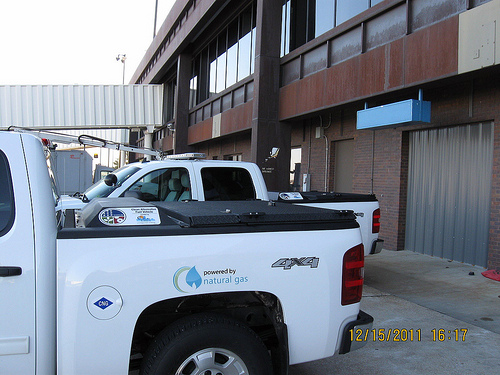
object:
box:
[356, 99, 432, 130]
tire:
[142, 312, 276, 373]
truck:
[2, 129, 363, 371]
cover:
[84, 284, 123, 321]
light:
[343, 245, 366, 308]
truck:
[64, 158, 384, 255]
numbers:
[271, 257, 292, 270]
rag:
[481, 267, 500, 283]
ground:
[289, 246, 499, 373]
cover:
[151, 197, 362, 235]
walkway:
[2, 81, 169, 131]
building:
[129, 0, 499, 269]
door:
[407, 121, 493, 267]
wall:
[301, 118, 407, 250]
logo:
[172, 265, 251, 293]